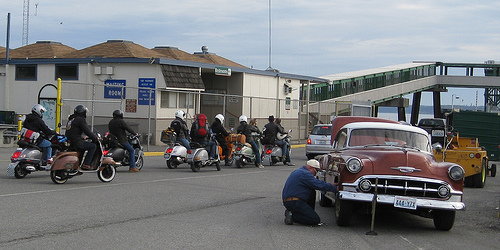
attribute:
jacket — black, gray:
[60, 110, 111, 153]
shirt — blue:
[269, 148, 333, 238]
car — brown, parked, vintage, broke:
[308, 76, 495, 221]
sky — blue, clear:
[70, 15, 187, 42]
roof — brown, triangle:
[15, 30, 271, 65]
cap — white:
[299, 143, 342, 185]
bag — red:
[185, 97, 222, 158]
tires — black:
[322, 186, 362, 228]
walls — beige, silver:
[77, 66, 249, 155]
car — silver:
[281, 113, 349, 173]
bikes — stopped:
[23, 123, 305, 186]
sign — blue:
[85, 67, 183, 118]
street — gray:
[67, 158, 269, 239]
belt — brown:
[279, 192, 304, 210]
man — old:
[288, 155, 333, 181]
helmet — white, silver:
[171, 110, 197, 124]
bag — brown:
[219, 125, 253, 149]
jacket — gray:
[167, 116, 193, 146]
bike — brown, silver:
[39, 131, 151, 218]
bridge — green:
[314, 68, 458, 109]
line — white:
[123, 171, 221, 192]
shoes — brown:
[123, 162, 171, 188]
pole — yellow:
[45, 60, 107, 198]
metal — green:
[451, 106, 496, 158]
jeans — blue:
[259, 179, 339, 244]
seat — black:
[101, 129, 138, 146]